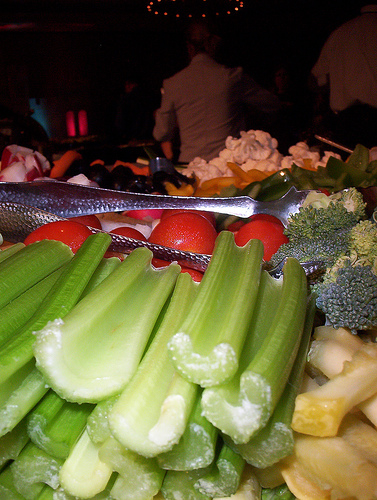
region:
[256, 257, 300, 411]
a crisp stalk of celery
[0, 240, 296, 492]
several stalks of celery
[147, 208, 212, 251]
a bright cherry tomato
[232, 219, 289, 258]
a bright cherry tomato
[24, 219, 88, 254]
a bright cherry tomato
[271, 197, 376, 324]
small heads of broccoli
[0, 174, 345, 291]
a small silver tong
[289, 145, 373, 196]
fresh sliced bell peppers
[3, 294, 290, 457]
Celery is on the table.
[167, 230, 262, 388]
The celery is cut into stalks.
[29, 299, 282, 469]
The celery is stacked on top of each other.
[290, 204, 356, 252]
Broccoli is on the table.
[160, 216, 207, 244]
Tomatoes are on the table.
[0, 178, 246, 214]
A pair of tongs are on the vegetables.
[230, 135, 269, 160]
Cauliflower is on the table.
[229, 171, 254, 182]
Yellow peppers are on the table.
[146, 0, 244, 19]
A light is lit on the ceiling.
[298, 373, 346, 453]
White stuff on top of food.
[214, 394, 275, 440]
White stuff on celery.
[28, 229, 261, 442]
Bunch of cut up celery.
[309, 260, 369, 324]
Small piece of broccoli.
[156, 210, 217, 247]
Small tomato on platter.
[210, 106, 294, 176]
White stuck on platter.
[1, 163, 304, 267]
Utensil for grabbing on platter.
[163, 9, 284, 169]
Man wearing a blazer.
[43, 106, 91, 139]
Red light in the back.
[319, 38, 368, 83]
Man with white shirt on the side.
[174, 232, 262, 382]
a stick of celary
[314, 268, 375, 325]
a head of broccoli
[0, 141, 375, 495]
an assortment of fruits and vegetables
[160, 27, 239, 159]
a woman with her back turned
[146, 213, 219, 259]
a ripe juicy tomato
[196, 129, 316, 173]
a bunch of white cauliflower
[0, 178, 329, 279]
a pair of metallic tongs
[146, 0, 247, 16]
a circular light fixture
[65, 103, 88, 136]
a red shaded lamp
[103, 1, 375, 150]
a group of partygoers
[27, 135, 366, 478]
celery stacked up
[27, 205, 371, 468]
green celery stacked up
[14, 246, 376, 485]
cut celery stacked up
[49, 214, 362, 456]
cut green celery stack up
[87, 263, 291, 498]
cut green celery stacked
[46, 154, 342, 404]
tomatoes in a pile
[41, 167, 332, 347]
cherry tomatos in a pile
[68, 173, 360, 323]
small cherry tomatos in a pile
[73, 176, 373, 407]
a pile of cherry tomatos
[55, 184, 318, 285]
a pile of tomatoes